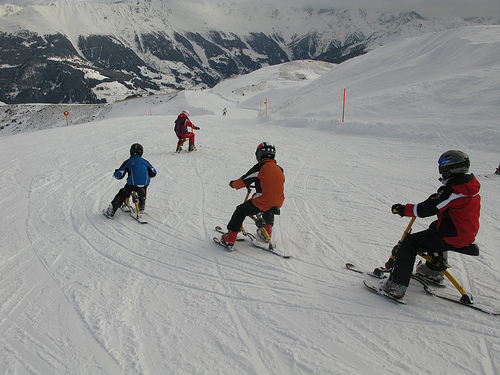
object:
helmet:
[130, 143, 144, 156]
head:
[129, 143, 143, 157]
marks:
[475, 334, 500, 375]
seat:
[448, 244, 479, 256]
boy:
[221, 141, 286, 247]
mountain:
[0, 0, 500, 104]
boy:
[379, 150, 481, 301]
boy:
[173, 110, 200, 153]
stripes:
[217, 291, 267, 375]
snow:
[0, 25, 499, 375]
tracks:
[399, 302, 500, 338]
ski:
[129, 213, 148, 224]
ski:
[213, 236, 237, 251]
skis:
[424, 282, 500, 315]